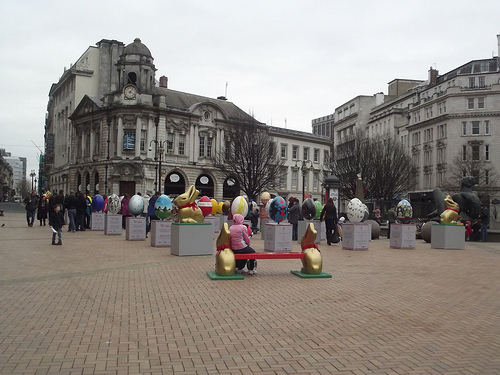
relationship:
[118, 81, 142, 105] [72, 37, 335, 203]
clock on building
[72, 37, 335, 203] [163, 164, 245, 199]
building has arches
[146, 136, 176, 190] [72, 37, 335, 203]
streetlamp near building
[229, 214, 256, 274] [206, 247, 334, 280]
woman sitting on bench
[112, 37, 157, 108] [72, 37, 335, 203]
tower on building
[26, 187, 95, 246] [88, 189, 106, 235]
people looking at egg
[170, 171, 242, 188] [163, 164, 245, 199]
clocks in arches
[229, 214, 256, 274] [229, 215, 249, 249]
woman in a hoodie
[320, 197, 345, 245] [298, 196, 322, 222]
person standing near egg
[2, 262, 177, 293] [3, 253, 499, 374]
bricks are on sidewalk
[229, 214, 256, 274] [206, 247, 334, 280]
woman on bench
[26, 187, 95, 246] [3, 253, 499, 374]
group on sidewalk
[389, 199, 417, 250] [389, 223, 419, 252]
statue on stand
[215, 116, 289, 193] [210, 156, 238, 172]
trees have branches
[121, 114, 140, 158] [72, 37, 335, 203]
window in building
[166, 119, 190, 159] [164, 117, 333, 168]
window in sections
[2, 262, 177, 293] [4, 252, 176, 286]
bricks in a line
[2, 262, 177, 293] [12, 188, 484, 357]
bricks in town square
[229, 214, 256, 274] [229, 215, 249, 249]
woman in jacket